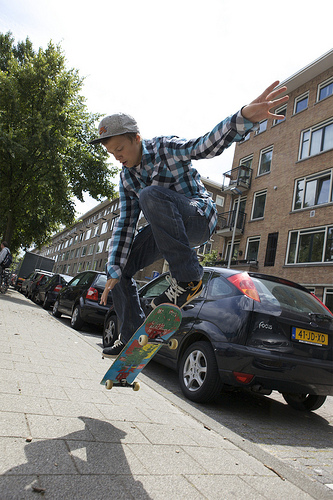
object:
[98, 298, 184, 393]
skateboard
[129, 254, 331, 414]
car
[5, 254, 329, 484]
street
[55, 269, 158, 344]
car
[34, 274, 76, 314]
car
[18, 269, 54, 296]
car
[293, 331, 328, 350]
license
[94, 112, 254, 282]
shirt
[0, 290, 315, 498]
sidewalk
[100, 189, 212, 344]
jeans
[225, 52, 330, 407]
building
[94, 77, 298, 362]
boy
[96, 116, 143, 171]
head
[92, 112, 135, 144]
hat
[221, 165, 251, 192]
balcony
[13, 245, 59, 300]
truck